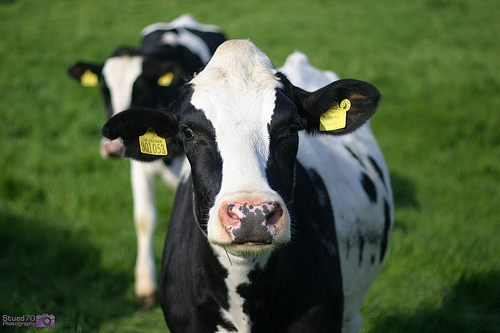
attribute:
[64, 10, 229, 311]
cow — looking, female, small, blurry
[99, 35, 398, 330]
cow — looking, male, black, white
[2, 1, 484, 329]
grass — blurry, green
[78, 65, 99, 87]
tag — yellow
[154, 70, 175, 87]
tag — yellow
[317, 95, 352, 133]
tag — yellow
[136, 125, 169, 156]
tag — yellow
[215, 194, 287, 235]
nose — pink, black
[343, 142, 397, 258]
spots — black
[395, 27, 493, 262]
field — grassy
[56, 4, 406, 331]
cows — black, white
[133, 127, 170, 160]
tag — yellow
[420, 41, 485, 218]
grass — green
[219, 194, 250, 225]
nose — pink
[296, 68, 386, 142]
ear — black